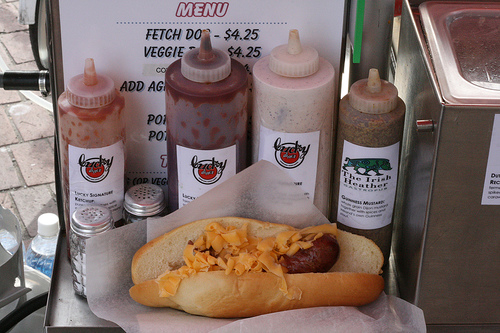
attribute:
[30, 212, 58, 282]
bottle — water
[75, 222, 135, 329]
wrapper — white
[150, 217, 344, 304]
cheese — orange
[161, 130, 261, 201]
lable — white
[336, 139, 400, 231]
label — green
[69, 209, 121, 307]
shaker — salt 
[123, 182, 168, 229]
shaker — pepper 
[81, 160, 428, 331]
tissue paper — white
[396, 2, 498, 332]
bin — metal 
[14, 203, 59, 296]
water bottle — plastic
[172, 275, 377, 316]
bun — white 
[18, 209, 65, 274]
bottle — water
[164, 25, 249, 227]
bottles — open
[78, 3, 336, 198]
menu — white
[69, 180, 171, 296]
shaker — salt , pepper 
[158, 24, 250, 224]
sauce — bbq 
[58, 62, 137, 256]
bottle — ketchup 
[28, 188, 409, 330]
tray — metal 